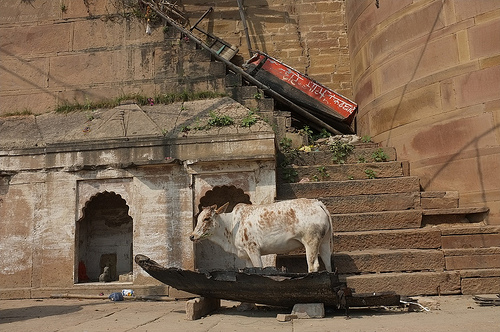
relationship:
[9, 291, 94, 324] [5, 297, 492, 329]
shadow on ground